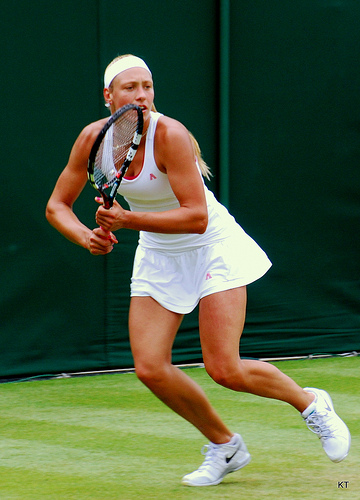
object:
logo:
[335, 480, 349, 490]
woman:
[44, 53, 351, 488]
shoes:
[180, 385, 354, 487]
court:
[0, 354, 359, 500]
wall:
[1, 1, 359, 367]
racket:
[87, 103, 144, 241]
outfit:
[99, 112, 273, 314]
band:
[104, 55, 153, 89]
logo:
[149, 173, 156, 180]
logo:
[226, 444, 241, 464]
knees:
[133, 351, 170, 388]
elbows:
[45, 195, 72, 228]